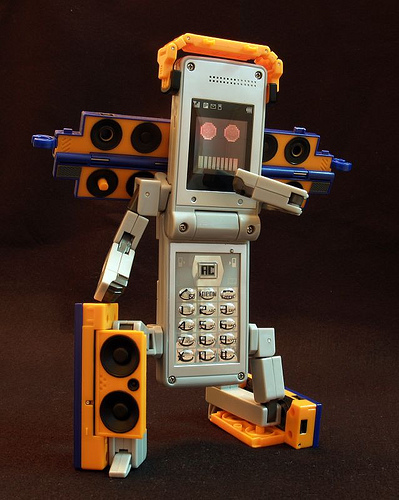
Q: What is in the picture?
A: A cellphone.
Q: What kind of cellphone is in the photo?
A: Robot.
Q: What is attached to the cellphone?
A: Legs and arms.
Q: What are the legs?
A: Speakers.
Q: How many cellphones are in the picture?
A: One.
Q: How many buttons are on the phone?
A: Twelve.